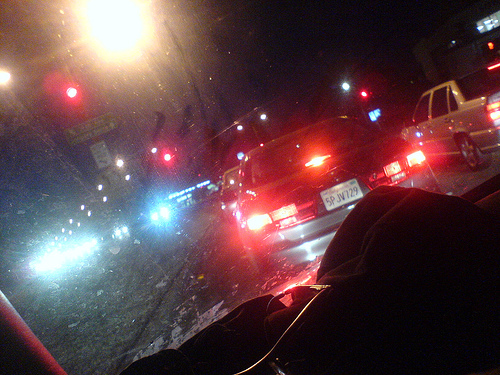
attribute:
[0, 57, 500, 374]
cars — stopped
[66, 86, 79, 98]
light — red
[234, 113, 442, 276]
car — stopped, black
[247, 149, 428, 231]
brake lights — on, red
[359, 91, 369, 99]
street light — red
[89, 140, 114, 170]
sign — white, black, hanging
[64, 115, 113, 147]
letter — white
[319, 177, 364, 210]
license plate — white, black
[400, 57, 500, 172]
car — silver, gray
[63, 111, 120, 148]
sign — green, white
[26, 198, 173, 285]
headlights — on, bright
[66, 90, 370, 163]
traffic lights — red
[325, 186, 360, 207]
letters — black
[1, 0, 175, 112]
street light — white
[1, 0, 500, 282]
lights — on, white, red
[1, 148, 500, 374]
road — dark grey, black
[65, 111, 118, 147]
lettering — white